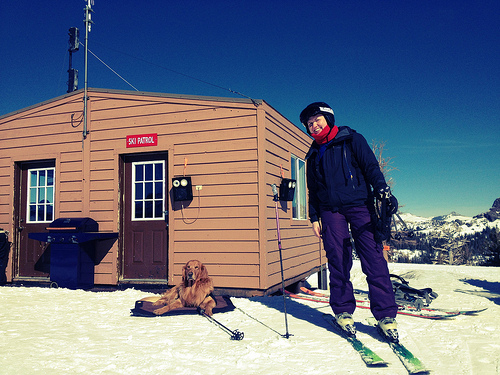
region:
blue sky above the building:
[164, 8, 309, 75]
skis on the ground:
[339, 305, 419, 372]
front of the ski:
[353, 343, 391, 373]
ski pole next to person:
[250, 200, 304, 358]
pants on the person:
[309, 203, 393, 319]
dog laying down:
[148, 243, 235, 325]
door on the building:
[98, 135, 190, 272]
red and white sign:
[115, 123, 170, 157]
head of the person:
[286, 82, 350, 149]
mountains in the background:
[423, 199, 482, 241]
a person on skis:
[296, 105, 429, 374]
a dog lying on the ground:
[143, 260, 215, 314]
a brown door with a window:
[119, 152, 169, 284]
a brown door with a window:
[14, 160, 52, 280]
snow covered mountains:
[388, 195, 496, 265]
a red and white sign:
[123, 133, 156, 147]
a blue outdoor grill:
[28, 218, 118, 285]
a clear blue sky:
[1, 0, 498, 215]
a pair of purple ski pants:
[317, 203, 398, 318]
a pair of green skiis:
[324, 314, 429, 374]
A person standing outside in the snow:
[298, 103, 399, 341]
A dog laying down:
[155, 259, 215, 316]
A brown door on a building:
[115, 150, 168, 283]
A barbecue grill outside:
[25, 215, 116, 285]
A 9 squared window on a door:
[131, 160, 164, 220]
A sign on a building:
[125, 131, 156, 146]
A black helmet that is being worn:
[297, 101, 335, 138]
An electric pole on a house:
[81, 0, 92, 140]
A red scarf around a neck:
[312, 125, 337, 141]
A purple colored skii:
[266, 183, 291, 338]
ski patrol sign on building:
[125, 131, 158, 144]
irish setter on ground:
[131, 257, 236, 314]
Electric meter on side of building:
[172, 175, 202, 224]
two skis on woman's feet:
[333, 303, 435, 374]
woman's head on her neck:
[292, 95, 346, 144]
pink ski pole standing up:
[268, 180, 298, 341]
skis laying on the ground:
[385, 253, 475, 330]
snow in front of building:
[37, 306, 120, 363]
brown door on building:
[122, 160, 172, 276]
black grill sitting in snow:
[25, 208, 120, 283]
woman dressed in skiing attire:
[300, 95, 417, 337]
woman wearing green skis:
[332, 310, 436, 373]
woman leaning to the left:
[298, 98, 400, 276]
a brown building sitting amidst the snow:
[3, 85, 324, 342]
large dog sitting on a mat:
[132, 257, 233, 318]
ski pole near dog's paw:
[192, 297, 245, 342]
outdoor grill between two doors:
[9, 151, 172, 293]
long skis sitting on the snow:
[287, 274, 490, 325]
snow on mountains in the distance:
[387, 208, 498, 265]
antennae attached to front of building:
[75, 1, 97, 139]